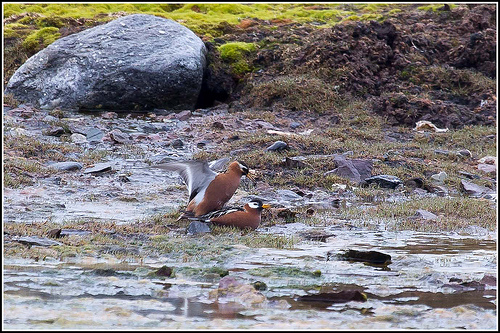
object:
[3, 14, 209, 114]
boulder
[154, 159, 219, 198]
wing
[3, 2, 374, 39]
grass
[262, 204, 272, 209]
beak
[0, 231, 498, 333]
pond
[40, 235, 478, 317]
land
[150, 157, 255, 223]
bird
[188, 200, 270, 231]
bird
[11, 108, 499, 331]
ground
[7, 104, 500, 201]
rocks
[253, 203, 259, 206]
eye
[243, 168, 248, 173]
eye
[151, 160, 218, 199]
feather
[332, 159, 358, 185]
sharp rocks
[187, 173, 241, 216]
bodies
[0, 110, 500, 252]
beach